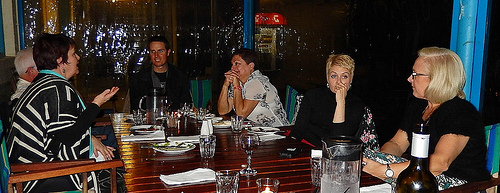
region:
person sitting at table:
[368, 45, 490, 177]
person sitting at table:
[301, 51, 363, 151]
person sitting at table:
[221, 48, 285, 126]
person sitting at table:
[131, 36, 194, 108]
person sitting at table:
[8, 50, 38, 102]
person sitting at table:
[12, 34, 120, 189]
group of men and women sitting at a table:
[3, 35, 495, 191]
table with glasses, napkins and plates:
[109, 95, 391, 188]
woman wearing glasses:
[361, 45, 485, 177]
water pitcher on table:
[318, 132, 368, 192]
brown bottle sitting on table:
[393, 118, 438, 191]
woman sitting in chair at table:
[0, 30, 120, 192]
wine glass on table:
[238, 128, 261, 175]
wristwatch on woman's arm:
[383, 161, 394, 181]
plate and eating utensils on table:
[138, 139, 196, 156]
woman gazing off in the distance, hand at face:
[288, 50, 370, 150]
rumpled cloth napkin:
[158, 165, 217, 185]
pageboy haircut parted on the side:
[406, 42, 468, 104]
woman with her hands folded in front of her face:
[215, 47, 290, 127]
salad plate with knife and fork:
[141, 137, 198, 155]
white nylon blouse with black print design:
[226, 67, 292, 127]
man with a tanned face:
[128, 35, 193, 112]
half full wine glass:
[238, 129, 260, 176]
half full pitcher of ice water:
[318, 139, 364, 191]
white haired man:
[8, 47, 39, 100]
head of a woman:
[373, 35, 475, 118]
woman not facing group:
[300, 51, 373, 120]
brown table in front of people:
[241, 145, 308, 187]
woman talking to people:
[31, 37, 96, 94]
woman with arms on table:
[194, 47, 275, 124]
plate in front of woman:
[143, 130, 200, 170]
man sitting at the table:
[131, 20, 196, 91]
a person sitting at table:
[393, 37, 499, 190]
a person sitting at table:
[308, 31, 369, 161]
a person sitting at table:
[219, 51, 285, 120]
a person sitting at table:
[129, 35, 194, 129]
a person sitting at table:
[26, 40, 98, 167]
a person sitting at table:
[5, 41, 44, 101]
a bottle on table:
[382, 108, 435, 191]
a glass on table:
[230, 122, 262, 164]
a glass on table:
[169, 117, 220, 168]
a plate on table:
[142, 131, 193, 175]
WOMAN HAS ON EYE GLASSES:
[408, 70, 428, 78]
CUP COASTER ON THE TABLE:
[256, 173, 282, 188]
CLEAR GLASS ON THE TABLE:
[213, 170, 236, 192]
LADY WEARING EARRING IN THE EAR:
[324, 82, 329, 89]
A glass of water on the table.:
[196, 128, 226, 158]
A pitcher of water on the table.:
[316, 135, 368, 190]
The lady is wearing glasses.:
[403, 62, 430, 79]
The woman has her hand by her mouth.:
[329, 73, 354, 101]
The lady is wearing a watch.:
[380, 155, 390, 182]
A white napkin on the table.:
[154, 163, 226, 189]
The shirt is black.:
[296, 91, 371, 142]